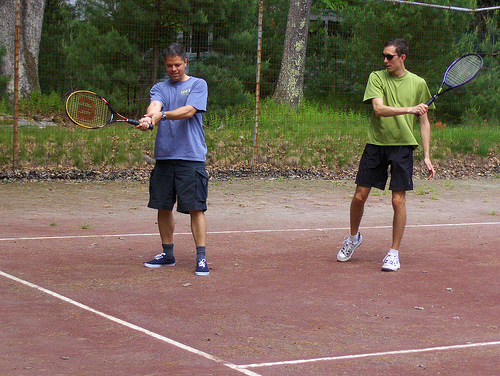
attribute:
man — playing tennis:
[139, 44, 212, 276]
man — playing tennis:
[334, 38, 437, 272]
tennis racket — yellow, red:
[64, 90, 154, 131]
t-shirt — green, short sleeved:
[362, 68, 437, 147]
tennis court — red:
[1, 218, 498, 375]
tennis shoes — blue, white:
[143, 254, 211, 277]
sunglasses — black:
[380, 53, 403, 59]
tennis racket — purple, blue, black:
[427, 52, 484, 103]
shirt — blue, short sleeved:
[149, 77, 208, 160]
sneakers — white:
[333, 232, 402, 272]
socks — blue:
[159, 241, 207, 257]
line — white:
[241, 334, 500, 369]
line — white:
[0, 268, 234, 375]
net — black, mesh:
[22, 2, 256, 170]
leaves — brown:
[415, 157, 499, 180]